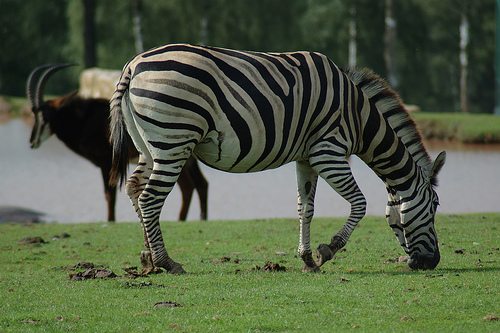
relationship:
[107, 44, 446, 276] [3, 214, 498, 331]
zebra in grass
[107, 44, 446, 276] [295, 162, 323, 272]
zebra has leg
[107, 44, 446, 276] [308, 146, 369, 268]
zebra has leg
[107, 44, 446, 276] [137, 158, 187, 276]
zebra has leg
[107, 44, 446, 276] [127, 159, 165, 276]
zebra has leg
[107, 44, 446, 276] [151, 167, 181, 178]
zebra has stripe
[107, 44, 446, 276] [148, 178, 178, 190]
zebra has stripe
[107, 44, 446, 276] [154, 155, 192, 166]
zebra has stripe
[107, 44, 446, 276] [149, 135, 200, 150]
zebra has stripe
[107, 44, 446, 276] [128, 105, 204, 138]
zebra has stripe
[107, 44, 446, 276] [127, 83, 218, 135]
zebra has stripe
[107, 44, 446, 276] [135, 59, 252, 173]
zebra has stripe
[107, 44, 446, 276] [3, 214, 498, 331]
zebra eats grass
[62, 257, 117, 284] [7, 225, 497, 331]
dirt on ground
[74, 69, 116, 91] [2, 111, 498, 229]
rock on side of lake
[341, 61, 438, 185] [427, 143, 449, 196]
mane fur between zebra ear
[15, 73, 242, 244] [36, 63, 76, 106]
ram has a horn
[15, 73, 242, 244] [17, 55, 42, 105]
ram has a horn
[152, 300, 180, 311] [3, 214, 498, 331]
indent in grass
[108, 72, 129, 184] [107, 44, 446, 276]
tail on zebra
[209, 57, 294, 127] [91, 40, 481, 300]
stripes on zebra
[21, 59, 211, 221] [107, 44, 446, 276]
antelope behind zebra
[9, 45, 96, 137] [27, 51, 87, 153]
horns of antelope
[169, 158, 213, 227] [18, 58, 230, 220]
knees of antelope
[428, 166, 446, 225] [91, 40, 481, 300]
eyelash of zebra